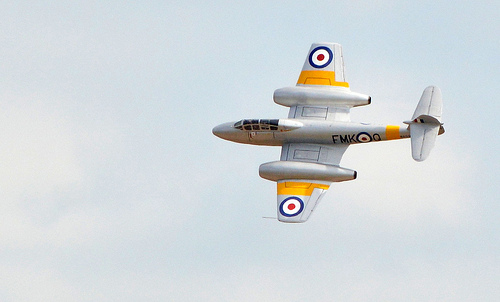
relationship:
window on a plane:
[234, 118, 279, 131] [210, 26, 476, 248]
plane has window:
[209, 35, 449, 225] [235, 113, 277, 133]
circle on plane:
[308, 45, 334, 70] [188, 36, 469, 252]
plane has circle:
[212, 40, 447, 224] [307, 43, 335, 68]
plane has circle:
[212, 40, 447, 224] [278, 193, 305, 218]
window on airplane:
[234, 118, 279, 131] [204, 64, 414, 216]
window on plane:
[234, 118, 279, 131] [209, 35, 449, 225]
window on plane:
[241, 116, 279, 134] [220, 35, 440, 229]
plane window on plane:
[231, 112, 285, 135] [194, 47, 404, 216]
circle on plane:
[305, 45, 336, 70] [209, 35, 449, 225]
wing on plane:
[292, 37, 349, 85] [209, 35, 449, 225]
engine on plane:
[257, 157, 358, 182] [209, 35, 449, 225]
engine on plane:
[273, 86, 370, 108] [209, 35, 449, 225]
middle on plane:
[274, 113, 384, 146] [209, 35, 449, 225]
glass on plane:
[233, 118, 279, 131] [209, 35, 449, 225]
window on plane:
[234, 118, 279, 131] [207, 49, 454, 234]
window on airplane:
[234, 118, 279, 131] [207, 27, 450, 227]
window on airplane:
[234, 118, 279, 131] [169, 26, 413, 220]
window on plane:
[234, 118, 279, 131] [212, 40, 447, 224]